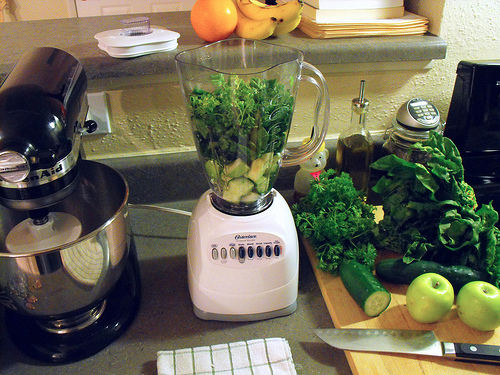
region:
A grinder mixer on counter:
[186, 187, 297, 320]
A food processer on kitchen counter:
[0, 47, 143, 363]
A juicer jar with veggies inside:
[173, 36, 330, 214]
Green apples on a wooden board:
[405, 271, 499, 331]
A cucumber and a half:
[338, 258, 480, 317]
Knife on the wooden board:
[311, 328, 498, 362]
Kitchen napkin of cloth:
[155, 335, 294, 373]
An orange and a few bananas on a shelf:
[190, 0, 304, 40]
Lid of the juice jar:
[92, 16, 179, 56]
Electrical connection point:
[80, 92, 110, 134]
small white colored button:
[409, 105, 421, 112]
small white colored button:
[419, 103, 426, 108]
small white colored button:
[425, 103, 432, 109]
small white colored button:
[412, 108, 422, 113]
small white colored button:
[420, 108, 430, 112]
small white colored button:
[427, 107, 434, 112]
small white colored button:
[415, 111, 425, 119]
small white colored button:
[420, 110, 434, 117]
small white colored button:
[429, 109, 437, 116]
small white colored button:
[425, 115, 434, 118]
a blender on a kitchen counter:
[171, 36, 329, 320]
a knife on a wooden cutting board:
[313, 325, 499, 364]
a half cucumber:
[338, 255, 389, 317]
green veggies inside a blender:
[186, 70, 296, 202]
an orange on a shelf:
[193, 0, 238, 42]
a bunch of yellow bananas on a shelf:
[233, 1, 303, 38]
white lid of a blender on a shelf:
[96, 15, 181, 57]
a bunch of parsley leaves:
[291, 168, 378, 272]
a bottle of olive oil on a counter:
[335, 78, 371, 201]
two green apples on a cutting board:
[406, 273, 498, 331]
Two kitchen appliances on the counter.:
[9, 22, 322, 366]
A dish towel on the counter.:
[144, 330, 311, 372]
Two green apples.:
[403, 265, 498, 335]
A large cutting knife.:
[311, 317, 497, 368]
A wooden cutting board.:
[302, 213, 492, 373]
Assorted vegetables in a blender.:
[171, 34, 323, 212]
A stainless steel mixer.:
[3, 41, 145, 368]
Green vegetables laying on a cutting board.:
[307, 148, 492, 310]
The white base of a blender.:
[181, 190, 302, 321]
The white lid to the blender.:
[92, 13, 177, 64]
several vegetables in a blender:
[172, 34, 302, 202]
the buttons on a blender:
[208, 238, 284, 266]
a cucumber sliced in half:
[329, 256, 395, 317]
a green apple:
[405, 265, 454, 329]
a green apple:
[453, 273, 498, 337]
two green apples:
[405, 268, 499, 333]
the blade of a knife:
[309, 328, 440, 360]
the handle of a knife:
[442, 337, 499, 365]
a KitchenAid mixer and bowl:
[1, 43, 147, 360]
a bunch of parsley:
[308, 183, 360, 250]